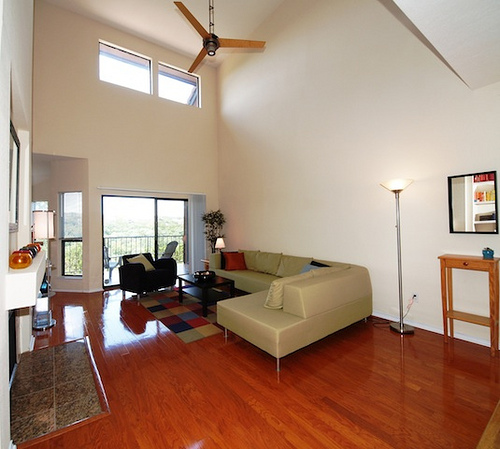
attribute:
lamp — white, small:
[209, 234, 230, 254]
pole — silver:
[388, 194, 416, 334]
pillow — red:
[215, 251, 249, 275]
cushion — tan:
[241, 248, 311, 279]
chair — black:
[117, 250, 182, 295]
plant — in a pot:
[192, 204, 226, 256]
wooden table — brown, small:
[433, 249, 499, 357]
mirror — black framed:
[441, 166, 499, 241]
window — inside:
[93, 35, 209, 113]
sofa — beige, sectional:
[199, 242, 378, 374]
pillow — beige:
[123, 253, 158, 275]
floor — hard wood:
[19, 292, 498, 448]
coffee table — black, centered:
[173, 267, 239, 316]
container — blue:
[480, 244, 498, 263]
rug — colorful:
[130, 285, 246, 348]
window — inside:
[50, 189, 86, 281]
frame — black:
[441, 169, 499, 239]